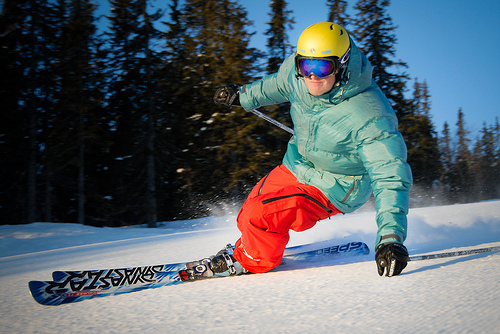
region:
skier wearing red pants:
[230, 160, 342, 273]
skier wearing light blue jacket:
[240, 38, 412, 250]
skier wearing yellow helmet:
[291, 21, 351, 78]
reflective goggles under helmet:
[292, 55, 337, 78]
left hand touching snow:
[0, 201, 499, 333]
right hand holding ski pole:
[213, 83, 295, 135]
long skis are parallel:
[26, 236, 370, 306]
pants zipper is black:
[260, 191, 331, 212]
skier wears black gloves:
[213, 79, 410, 277]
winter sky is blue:
[15, 0, 498, 201]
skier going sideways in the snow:
[11, 14, 436, 304]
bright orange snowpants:
[216, 153, 346, 285]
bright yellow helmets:
[285, 17, 355, 99]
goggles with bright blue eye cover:
[288, 48, 351, 87]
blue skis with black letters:
[11, 221, 391, 318]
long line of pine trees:
[0, 5, 466, 230]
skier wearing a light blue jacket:
[228, 31, 414, 237]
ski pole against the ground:
[379, 237, 493, 269]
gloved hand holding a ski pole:
[208, 83, 296, 150]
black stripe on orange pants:
[262, 190, 331, 218]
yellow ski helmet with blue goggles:
[298, 28, 341, 78]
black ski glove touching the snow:
[376, 241, 403, 278]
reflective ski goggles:
[298, 57, 335, 75]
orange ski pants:
[257, 180, 287, 257]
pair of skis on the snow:
[25, 266, 201, 297]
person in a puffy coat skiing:
[33, 15, 421, 295]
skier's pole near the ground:
[382, 241, 495, 259]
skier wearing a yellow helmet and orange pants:
[250, 27, 396, 232]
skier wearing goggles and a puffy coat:
[293, 22, 394, 208]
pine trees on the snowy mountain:
[22, 8, 208, 188]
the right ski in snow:
[51, 260, 171, 274]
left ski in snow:
[29, 277, 196, 294]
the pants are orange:
[236, 155, 324, 275]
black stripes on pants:
[256, 166, 322, 228]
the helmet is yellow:
[295, 23, 358, 50]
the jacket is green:
[289, 93, 407, 193]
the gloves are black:
[378, 240, 430, 295]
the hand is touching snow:
[358, 230, 446, 305]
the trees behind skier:
[162, 24, 414, 231]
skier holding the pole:
[213, 34, 386, 186]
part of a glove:
[388, 233, 392, 254]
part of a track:
[254, 203, 279, 222]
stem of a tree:
[152, 140, 171, 210]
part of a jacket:
[333, 135, 350, 158]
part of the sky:
[449, 117, 456, 144]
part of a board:
[77, 267, 91, 287]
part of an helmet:
[318, 38, 335, 51]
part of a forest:
[116, 125, 141, 142]